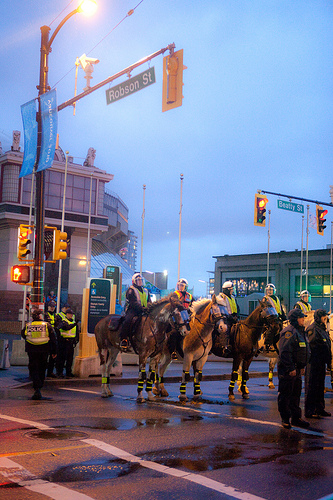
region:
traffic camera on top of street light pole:
[72, 53, 101, 116]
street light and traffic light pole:
[28, 0, 187, 318]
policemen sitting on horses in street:
[93, 273, 332, 403]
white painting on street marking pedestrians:
[0, 386, 331, 498]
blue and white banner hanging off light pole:
[16, 87, 59, 179]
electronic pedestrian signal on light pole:
[10, 264, 31, 283]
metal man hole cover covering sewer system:
[22, 427, 90, 442]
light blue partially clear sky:
[149, 122, 331, 170]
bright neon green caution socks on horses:
[100, 368, 273, 392]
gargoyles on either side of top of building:
[9, 128, 97, 166]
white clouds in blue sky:
[144, 13, 199, 45]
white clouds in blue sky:
[191, 146, 220, 168]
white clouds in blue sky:
[218, 106, 266, 140]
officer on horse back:
[107, 288, 187, 400]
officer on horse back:
[180, 293, 225, 400]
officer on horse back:
[223, 279, 276, 394]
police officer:
[18, 304, 50, 383]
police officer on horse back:
[92, 268, 189, 385]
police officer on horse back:
[180, 282, 224, 389]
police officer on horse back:
[212, 275, 273, 397]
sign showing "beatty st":
[274, 200, 309, 213]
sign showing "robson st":
[103, 70, 152, 107]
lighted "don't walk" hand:
[12, 265, 21, 284]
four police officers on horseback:
[114, 271, 319, 319]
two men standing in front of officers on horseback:
[279, 309, 332, 427]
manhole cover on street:
[22, 425, 89, 441]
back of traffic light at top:
[157, 47, 187, 115]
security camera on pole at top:
[78, 48, 100, 88]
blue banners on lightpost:
[16, 87, 60, 176]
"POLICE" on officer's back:
[23, 324, 51, 337]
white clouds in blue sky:
[181, 121, 219, 151]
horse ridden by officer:
[90, 294, 181, 395]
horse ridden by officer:
[189, 296, 226, 395]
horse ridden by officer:
[222, 290, 284, 402]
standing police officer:
[281, 302, 306, 412]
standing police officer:
[306, 296, 327, 431]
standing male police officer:
[51, 293, 82, 384]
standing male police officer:
[13, 307, 50, 384]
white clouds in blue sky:
[217, 128, 266, 159]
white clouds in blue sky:
[216, 68, 270, 108]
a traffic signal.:
[36, 32, 189, 153]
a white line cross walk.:
[1, 369, 332, 497]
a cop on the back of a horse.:
[78, 266, 199, 397]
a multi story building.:
[201, 241, 332, 317]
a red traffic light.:
[10, 220, 46, 264]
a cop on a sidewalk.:
[18, 289, 61, 380]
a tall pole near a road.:
[172, 169, 188, 286]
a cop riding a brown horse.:
[143, 266, 248, 404]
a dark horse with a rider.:
[193, 278, 290, 409]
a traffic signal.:
[245, 178, 330, 246]